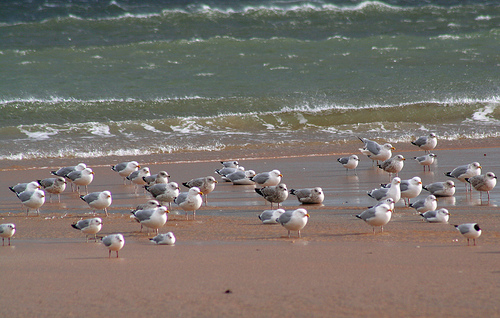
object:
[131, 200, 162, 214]
bird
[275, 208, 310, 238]
bird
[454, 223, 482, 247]
bird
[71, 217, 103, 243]
bird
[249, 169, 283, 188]
bird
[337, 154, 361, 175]
bird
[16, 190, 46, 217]
bird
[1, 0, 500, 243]
water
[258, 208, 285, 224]
bird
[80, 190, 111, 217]
bird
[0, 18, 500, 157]
water's surface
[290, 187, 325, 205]
bird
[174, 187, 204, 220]
bird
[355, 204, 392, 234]
bird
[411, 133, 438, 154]
bird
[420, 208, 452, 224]
bird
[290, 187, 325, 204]
birds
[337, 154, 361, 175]
birds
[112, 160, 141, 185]
birds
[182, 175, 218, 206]
birds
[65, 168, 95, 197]
birds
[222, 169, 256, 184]
seagull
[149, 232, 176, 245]
bird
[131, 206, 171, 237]
bird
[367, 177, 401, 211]
birds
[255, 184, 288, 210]
birds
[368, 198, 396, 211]
birds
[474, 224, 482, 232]
face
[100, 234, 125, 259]
bird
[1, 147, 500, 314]
beach